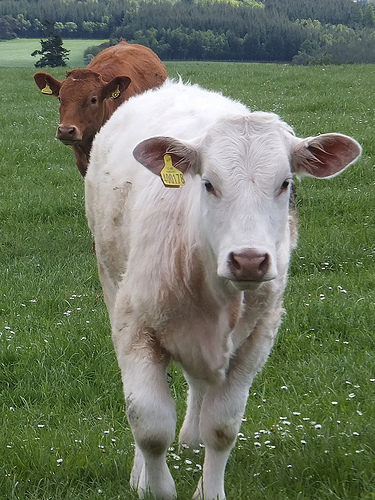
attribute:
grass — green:
[0, 162, 135, 497]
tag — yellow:
[159, 155, 186, 189]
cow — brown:
[44, 40, 162, 160]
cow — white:
[21, 77, 340, 222]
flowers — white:
[250, 398, 338, 455]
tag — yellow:
[39, 80, 53, 95]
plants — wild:
[2, 66, 374, 498]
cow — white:
[83, 78, 362, 499]